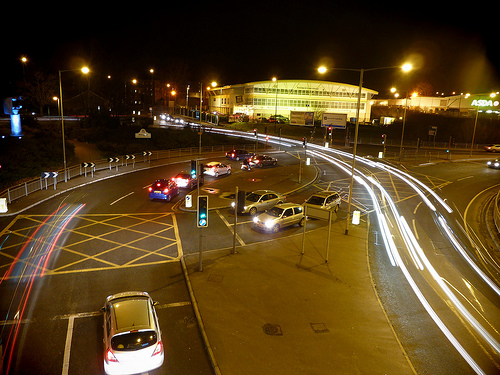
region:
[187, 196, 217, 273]
a stop light on a pole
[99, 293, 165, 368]
a white car stopped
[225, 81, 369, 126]
a white buiding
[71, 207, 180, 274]
yellow lines on a road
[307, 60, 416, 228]
pole lights on a pole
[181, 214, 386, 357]
a concrete divider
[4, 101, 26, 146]
neon blue sign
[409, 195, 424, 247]
a white dash line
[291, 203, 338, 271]
a sign on a pole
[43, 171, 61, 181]
black and white sign on a pole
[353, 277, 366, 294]
part of a pavement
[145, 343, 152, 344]
back of a car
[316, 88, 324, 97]
part of a building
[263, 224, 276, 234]
part of a light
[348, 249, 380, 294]
edge of a road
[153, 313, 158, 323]
side of a car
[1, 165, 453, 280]
crisscrossed lines in the intersection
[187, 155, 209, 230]
two green traffic lights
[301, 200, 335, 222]
the back of a traffic sign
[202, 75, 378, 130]
big building with a rounded roof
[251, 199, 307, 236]
a silver hatchback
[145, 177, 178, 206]
a blue car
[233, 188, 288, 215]
a silver sedan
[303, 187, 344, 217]
a silver van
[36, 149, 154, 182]
signs with arrows pointing to the right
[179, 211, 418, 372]
concrete in the middle of the intersection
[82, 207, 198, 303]
Yellow lines in road.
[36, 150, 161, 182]
Board is black and white color.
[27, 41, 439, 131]
Lights are on.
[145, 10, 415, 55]
Sky is black color.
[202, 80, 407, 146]
Building is white color.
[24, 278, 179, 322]
Road is grey color.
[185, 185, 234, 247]
green signal light is on.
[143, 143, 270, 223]
Red light in car rear is on.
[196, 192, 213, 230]
Intersection traffic light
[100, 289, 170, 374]
White SUV at intersection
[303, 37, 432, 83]
Two of many street lights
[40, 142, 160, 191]
Signs indicating a strong right turn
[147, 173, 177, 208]
Blue car with brake lights on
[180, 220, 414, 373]
Sidewalk median separating lanes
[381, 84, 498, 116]
Business called ASDA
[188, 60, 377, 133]
Large building to the left of the ASDA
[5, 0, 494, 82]
Dark night sky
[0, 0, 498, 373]
Busy street in the city